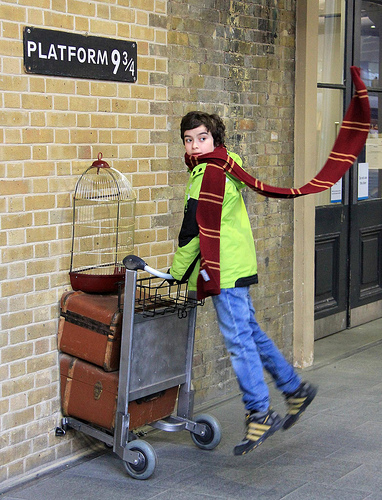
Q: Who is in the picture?
A: A boy.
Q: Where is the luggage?
A: On the cart.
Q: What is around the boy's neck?
A: A scarf.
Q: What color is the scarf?
A: Red.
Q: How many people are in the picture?
A: One.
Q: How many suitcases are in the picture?
A: Two.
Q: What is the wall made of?
A: Brick.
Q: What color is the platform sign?
A: Black.